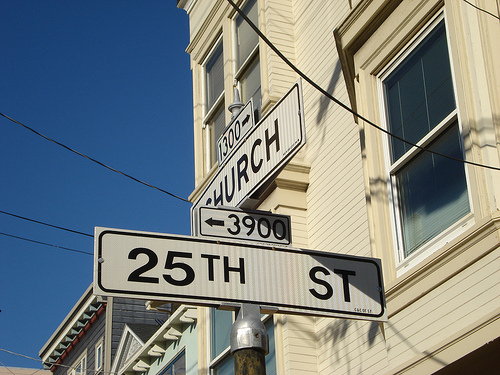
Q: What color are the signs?
A: White.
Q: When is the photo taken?
A: Day time.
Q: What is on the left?
A: Buildings.